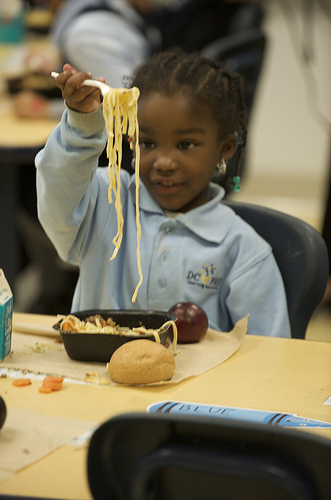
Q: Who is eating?
A: GIrl.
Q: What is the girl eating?
A: Spaghetti.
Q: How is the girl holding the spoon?
A: Up in the air.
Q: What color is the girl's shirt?
A: Blue.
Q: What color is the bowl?
A: Brown.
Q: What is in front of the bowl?
A: Bread roll.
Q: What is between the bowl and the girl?
A: Apple.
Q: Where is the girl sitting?
A: At the table.